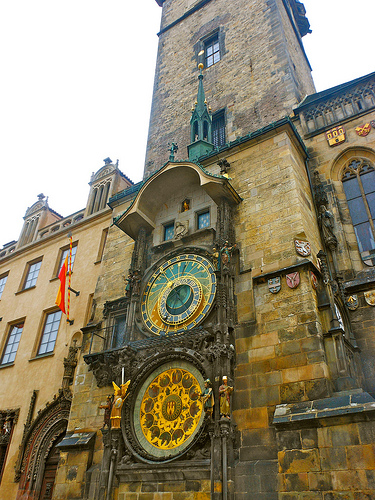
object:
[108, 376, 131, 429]
angle statue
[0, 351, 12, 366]
windows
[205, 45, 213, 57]
windows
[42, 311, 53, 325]
windows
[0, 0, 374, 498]
building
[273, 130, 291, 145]
stones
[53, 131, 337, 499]
wall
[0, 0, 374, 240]
sky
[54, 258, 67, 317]
flag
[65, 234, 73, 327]
pole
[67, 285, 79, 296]
clamps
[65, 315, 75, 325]
clamps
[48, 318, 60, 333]
window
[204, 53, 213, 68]
window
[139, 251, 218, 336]
clock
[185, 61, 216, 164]
steeple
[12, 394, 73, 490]
arhway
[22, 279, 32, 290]
window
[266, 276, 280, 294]
shields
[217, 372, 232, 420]
small statues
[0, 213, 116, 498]
wall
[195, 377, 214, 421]
decor